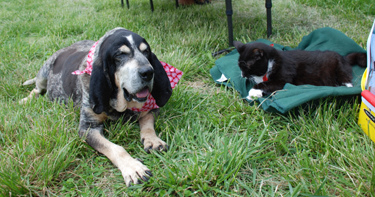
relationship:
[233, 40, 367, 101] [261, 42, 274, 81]
cat wearing collar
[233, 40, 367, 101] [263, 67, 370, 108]
cat on blanket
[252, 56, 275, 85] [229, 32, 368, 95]
ribbon on cat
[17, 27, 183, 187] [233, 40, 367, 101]
dog and cat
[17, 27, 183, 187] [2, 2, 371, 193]
dog in grass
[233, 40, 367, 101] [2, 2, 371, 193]
cat in grass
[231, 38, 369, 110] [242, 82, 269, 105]
cat with paws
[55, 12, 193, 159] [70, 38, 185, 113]
dog with scarf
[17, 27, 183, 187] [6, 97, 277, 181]
dog lying in grass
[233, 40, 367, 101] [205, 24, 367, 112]
cat laying on blanket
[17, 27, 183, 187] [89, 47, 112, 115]
dog with ear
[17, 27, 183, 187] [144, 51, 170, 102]
dog with ear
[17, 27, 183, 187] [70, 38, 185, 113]
dog with scarf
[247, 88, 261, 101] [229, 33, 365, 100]
paws on cat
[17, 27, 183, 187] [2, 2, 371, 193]
dog on grass